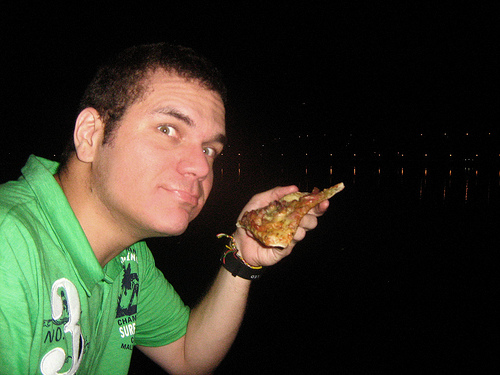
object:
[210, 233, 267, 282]
watch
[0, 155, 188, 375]
shirt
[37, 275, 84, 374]
3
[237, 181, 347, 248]
pizza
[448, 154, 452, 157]
lights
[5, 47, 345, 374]
man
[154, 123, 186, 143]
eye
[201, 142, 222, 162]
eye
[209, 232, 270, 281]
bracelet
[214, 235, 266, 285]
wrist